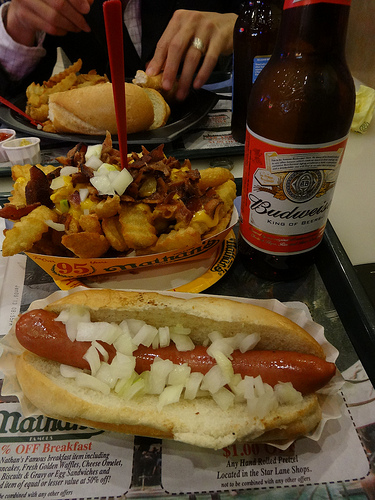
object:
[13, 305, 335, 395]
hot dog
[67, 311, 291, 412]
onions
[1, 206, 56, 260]
fry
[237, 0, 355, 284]
bottle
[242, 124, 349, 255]
label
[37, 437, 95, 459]
breakfast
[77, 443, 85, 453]
red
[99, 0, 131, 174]
fork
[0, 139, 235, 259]
fries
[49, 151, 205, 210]
various toppings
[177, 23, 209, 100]
finger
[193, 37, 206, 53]
ring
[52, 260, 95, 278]
number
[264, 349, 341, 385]
meat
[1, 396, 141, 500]
coupon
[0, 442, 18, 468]
percentage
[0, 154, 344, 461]
food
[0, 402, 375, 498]
paper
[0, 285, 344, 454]
plate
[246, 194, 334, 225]
writing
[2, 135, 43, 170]
cups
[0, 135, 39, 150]
sauce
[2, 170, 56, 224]
bacon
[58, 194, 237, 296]
plate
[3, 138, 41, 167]
paper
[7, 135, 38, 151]
mustard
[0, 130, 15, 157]
paper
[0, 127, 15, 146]
ketchup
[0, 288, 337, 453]
bun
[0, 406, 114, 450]
company name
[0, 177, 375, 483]
placemat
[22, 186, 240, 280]
paper basket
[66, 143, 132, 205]
onions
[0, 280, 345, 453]
paper dish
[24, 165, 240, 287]
container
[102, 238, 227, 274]
nathan's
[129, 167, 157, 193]
cheese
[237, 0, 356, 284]
beer